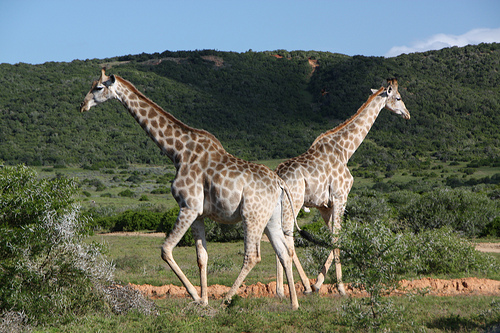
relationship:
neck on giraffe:
[117, 82, 199, 155] [76, 66, 312, 311]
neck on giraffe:
[336, 95, 380, 155] [275, 78, 410, 299]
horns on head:
[356, 71, 417, 139] [368, 77, 415, 127]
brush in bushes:
[41, 196, 160, 324] [1, 206, 151, 329]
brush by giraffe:
[0, 162, 148, 333] [76, 66, 312, 311]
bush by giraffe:
[296, 210, 496, 309] [275, 78, 410, 299]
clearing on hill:
[91, 46, 331, 73] [148, 40, 324, 106]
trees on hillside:
[431, 63, 476, 140] [386, 31, 477, 78]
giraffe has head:
[275, 78, 410, 299] [361, 72, 415, 123]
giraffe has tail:
[76, 66, 312, 311] [275, 179, 304, 231]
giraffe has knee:
[72, 62, 354, 315] [158, 243, 177, 260]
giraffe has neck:
[76, 66, 312, 311] [128, 81, 173, 146]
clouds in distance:
[382, 22, 499, 57] [2, 1, 484, 71]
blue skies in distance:
[54, 8, 134, 48] [1, 0, 485, 90]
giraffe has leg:
[76, 66, 312, 311] [156, 187, 200, 308]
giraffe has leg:
[76, 66, 312, 311] [188, 215, 216, 308]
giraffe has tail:
[76, 66, 312, 311] [276, 180, 323, 245]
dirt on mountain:
[204, 51, 228, 71] [178, 30, 301, 115]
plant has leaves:
[392, 183, 485, 237] [436, 193, 461, 214]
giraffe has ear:
[275, 77, 411, 301] [383, 80, 394, 97]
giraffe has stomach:
[72, 62, 354, 315] [206, 192, 241, 228]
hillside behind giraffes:
[12, 42, 498, 124] [213, 57, 440, 294]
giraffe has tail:
[76, 66, 312, 311] [279, 180, 306, 233]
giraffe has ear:
[76, 66, 312, 311] [108, 70, 116, 85]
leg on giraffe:
[217, 188, 274, 308] [76, 66, 312, 311]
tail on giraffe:
[279, 182, 314, 242] [76, 66, 312, 311]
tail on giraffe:
[272, 182, 312, 237] [258, 54, 444, 295]